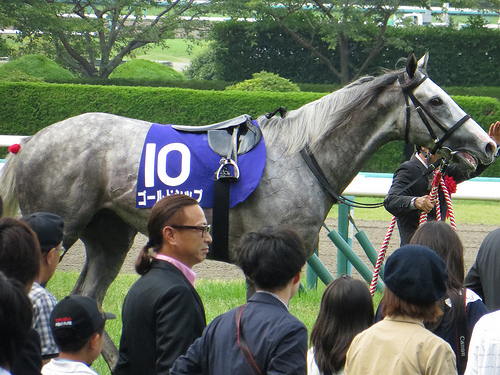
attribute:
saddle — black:
[140, 115, 265, 212]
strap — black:
[212, 160, 234, 261]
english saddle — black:
[173, 112, 264, 154]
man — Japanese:
[115, 195, 213, 373]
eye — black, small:
[428, 94, 443, 108]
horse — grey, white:
[3, 47, 498, 372]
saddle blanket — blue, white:
[129, 117, 268, 214]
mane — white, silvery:
[257, 55, 427, 157]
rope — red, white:
[367, 167, 455, 298]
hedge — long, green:
[3, 82, 498, 172]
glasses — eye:
[167, 220, 212, 237]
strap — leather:
[228, 304, 268, 372]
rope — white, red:
[365, 218, 392, 296]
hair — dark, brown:
[310, 273, 375, 373]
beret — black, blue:
[378, 242, 450, 306]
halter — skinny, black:
[413, 110, 440, 134]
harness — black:
[120, 99, 280, 259]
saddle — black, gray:
[171, 106, 263, 190]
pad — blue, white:
[137, 119, 266, 209]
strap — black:
[202, 173, 238, 261]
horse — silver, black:
[11, 32, 483, 302]